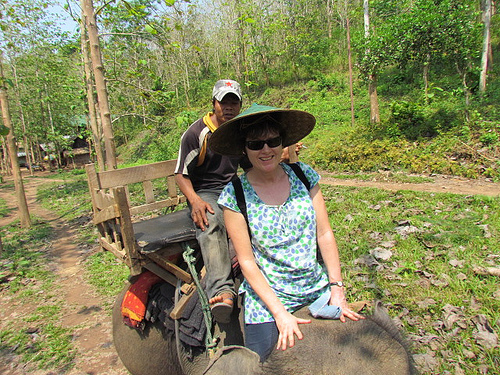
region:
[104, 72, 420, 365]
two people riding on elephant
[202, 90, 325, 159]
Asian style hat on woman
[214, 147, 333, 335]
short sleeved shirt with blue and green design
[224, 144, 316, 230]
black straps on woman's shoulders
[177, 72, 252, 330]
man on seat behind woman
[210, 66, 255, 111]
cap with red star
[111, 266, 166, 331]
colorful blanket under seat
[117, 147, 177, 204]
wood on back of seat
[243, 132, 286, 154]
sunglasses on woman's face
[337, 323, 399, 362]
hair on elephant's head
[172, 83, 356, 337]
two people on elephant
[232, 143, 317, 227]
black straps on shoulders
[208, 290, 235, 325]
man's foot in sandal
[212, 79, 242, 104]
hat with red star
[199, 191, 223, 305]
blue jeans on man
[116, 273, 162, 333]
colorful blanket on elephant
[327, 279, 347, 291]
watch on woman's wrist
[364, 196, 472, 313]
Brown leaves on grass.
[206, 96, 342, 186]
Woman wearing dark glasses.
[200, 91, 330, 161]
Woman in weird hat.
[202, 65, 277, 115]
Man with armhat with star on front.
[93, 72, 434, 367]
Two people riding an elephant.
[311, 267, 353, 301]
Watch on an arm.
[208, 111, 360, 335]
Woman with a green and blue print shirt.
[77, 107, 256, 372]
Seat on a elephants back.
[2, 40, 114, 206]
Green trees with brown trunks.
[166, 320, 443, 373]
Top of an elephants head.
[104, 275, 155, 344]
orange and yellow blanket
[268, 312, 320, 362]
woman's hand on animal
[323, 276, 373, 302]
black and white watch on woman's hand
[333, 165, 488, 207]
large brown path way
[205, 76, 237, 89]
red star on cap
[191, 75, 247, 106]
white cap with gray lines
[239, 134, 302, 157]
black sun glasse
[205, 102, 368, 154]
large green dome hat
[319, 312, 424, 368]
fur on animal's back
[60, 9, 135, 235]
large brown tree trunk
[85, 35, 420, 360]
man and woman on top of elephant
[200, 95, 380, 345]
woman riding on top of elephant neck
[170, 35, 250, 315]
man riding on bench attached to elephant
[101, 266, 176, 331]
orange and yellow blanket under bench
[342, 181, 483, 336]
grass littered with tree bark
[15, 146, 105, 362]
grass growing along brown path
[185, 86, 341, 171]
woman wearing wide-brimmed hat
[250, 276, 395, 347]
hands across the elephant's head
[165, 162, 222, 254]
hand resting on knee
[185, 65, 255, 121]
man wearing cap to shade face